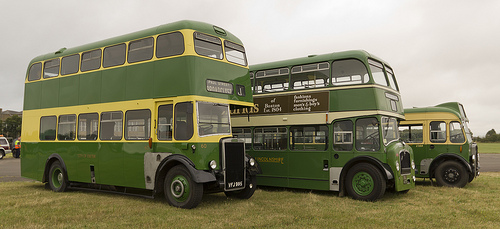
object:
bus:
[229, 48, 416, 201]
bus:
[399, 101, 478, 188]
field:
[0, 140, 498, 229]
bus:
[15, 19, 260, 208]